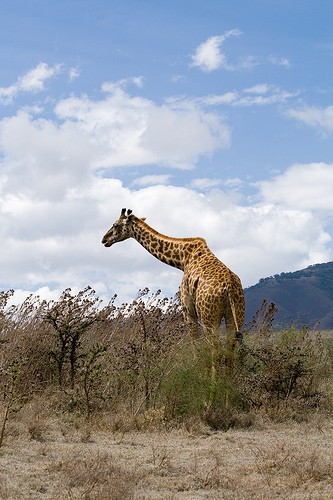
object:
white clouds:
[0, 26, 333, 314]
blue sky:
[0, 0, 333, 312]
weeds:
[0, 280, 330, 433]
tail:
[228, 285, 244, 345]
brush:
[163, 345, 232, 419]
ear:
[125, 214, 134, 225]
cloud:
[0, 0, 333, 317]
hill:
[242, 260, 332, 332]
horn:
[121, 208, 127, 216]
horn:
[127, 209, 132, 215]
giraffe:
[101, 207, 247, 423]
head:
[101, 207, 133, 247]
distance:
[234, 139, 330, 376]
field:
[0, 333, 333, 500]